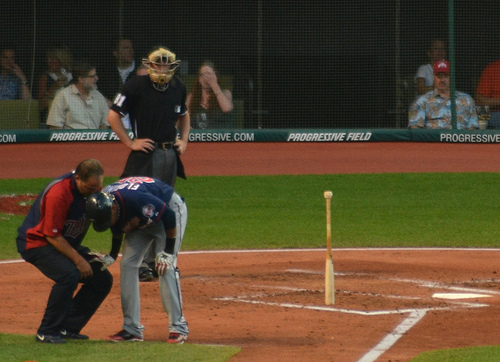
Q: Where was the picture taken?
A: It was taken at the field.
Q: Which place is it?
A: It is a field.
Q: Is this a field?
A: Yes, it is a field.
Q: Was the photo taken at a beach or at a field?
A: It was taken at a field.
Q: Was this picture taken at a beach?
A: No, the picture was taken in a field.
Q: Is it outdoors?
A: Yes, it is outdoors.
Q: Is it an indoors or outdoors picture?
A: It is outdoors.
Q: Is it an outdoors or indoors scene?
A: It is outdoors.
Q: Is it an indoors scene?
A: No, it is outdoors.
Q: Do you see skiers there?
A: No, there are no skiers.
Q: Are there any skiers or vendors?
A: No, there are no skiers or vendors.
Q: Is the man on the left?
A: Yes, the man is on the left of the image.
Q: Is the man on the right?
A: No, the man is on the left of the image.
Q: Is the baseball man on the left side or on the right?
A: The man is on the left of the image.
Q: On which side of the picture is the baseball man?
A: The man is on the left of the image.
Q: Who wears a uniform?
A: The man wears a uniform.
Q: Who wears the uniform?
A: The man wears a uniform.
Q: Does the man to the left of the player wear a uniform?
A: Yes, the man wears a uniform.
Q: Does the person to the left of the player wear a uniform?
A: Yes, the man wears a uniform.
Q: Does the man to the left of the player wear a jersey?
A: No, the man wears a uniform.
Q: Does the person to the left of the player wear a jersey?
A: No, the man wears a uniform.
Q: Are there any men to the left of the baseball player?
A: Yes, there is a man to the left of the player.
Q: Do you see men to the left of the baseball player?
A: Yes, there is a man to the left of the player.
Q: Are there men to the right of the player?
A: No, the man is to the left of the player.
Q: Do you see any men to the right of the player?
A: No, the man is to the left of the player.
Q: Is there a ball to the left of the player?
A: No, there is a man to the left of the player.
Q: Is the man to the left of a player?
A: Yes, the man is to the left of a player.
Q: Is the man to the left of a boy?
A: No, the man is to the left of a player.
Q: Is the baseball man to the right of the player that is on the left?
A: No, the man is to the left of the player.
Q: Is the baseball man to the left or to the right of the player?
A: The man is to the left of the player.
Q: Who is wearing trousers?
A: The man is wearing trousers.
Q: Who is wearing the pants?
A: The man is wearing trousers.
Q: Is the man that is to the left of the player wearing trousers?
A: Yes, the man is wearing trousers.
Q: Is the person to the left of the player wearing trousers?
A: Yes, the man is wearing trousers.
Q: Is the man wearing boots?
A: No, the man is wearing trousers.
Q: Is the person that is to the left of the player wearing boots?
A: No, the man is wearing trousers.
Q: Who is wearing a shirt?
A: The man is wearing a shirt.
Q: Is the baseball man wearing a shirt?
A: Yes, the man is wearing a shirt.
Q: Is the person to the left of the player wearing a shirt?
A: Yes, the man is wearing a shirt.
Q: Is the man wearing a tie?
A: No, the man is wearing a shirt.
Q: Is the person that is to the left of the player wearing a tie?
A: No, the man is wearing a shirt.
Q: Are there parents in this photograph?
A: No, there are no parents.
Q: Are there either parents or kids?
A: No, there are no parents or kids.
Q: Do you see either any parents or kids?
A: No, there are no parents or kids.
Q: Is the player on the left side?
A: Yes, the player is on the left of the image.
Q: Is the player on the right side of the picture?
A: No, the player is on the left of the image.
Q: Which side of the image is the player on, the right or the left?
A: The player is on the left of the image.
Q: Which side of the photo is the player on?
A: The player is on the left of the image.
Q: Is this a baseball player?
A: Yes, this is a baseball player.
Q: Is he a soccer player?
A: No, this is a baseball player.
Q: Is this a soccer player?
A: No, this is a baseball player.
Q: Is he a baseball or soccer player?
A: This is a baseball player.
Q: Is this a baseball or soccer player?
A: This is a baseball player.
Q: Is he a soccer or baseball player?
A: This is a baseball player.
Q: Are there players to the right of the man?
A: Yes, there is a player to the right of the man.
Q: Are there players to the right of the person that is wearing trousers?
A: Yes, there is a player to the right of the man.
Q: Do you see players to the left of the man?
A: No, the player is to the right of the man.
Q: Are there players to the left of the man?
A: No, the player is to the right of the man.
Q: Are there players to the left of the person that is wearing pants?
A: No, the player is to the right of the man.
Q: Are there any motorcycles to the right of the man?
A: No, there is a player to the right of the man.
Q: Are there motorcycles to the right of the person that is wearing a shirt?
A: No, there is a player to the right of the man.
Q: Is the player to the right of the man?
A: Yes, the player is to the right of the man.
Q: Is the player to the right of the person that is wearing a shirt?
A: Yes, the player is to the right of the man.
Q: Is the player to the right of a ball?
A: No, the player is to the right of the man.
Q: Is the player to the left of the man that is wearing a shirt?
A: No, the player is to the right of the man.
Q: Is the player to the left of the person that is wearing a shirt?
A: No, the player is to the right of the man.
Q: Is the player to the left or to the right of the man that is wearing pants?
A: The player is to the right of the man.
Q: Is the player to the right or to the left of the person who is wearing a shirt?
A: The player is to the right of the man.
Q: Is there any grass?
A: Yes, there is grass.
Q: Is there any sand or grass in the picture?
A: Yes, there is grass.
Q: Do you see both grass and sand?
A: No, there is grass but no sand.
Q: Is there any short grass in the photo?
A: Yes, there is short grass.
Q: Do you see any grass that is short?
A: Yes, there is short grass.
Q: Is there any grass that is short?
A: Yes, there is grass that is short.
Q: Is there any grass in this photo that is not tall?
A: Yes, there is short grass.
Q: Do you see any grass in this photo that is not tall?
A: Yes, there is short grass.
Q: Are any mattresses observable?
A: No, there are no mattresses.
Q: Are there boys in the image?
A: No, there are no boys.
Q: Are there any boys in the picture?
A: No, there are no boys.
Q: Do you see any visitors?
A: No, there are no visitors.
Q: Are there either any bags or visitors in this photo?
A: No, there are no visitors or bags.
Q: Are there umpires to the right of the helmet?
A: No, there is a lady to the right of the helmet.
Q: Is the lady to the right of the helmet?
A: Yes, the lady is to the right of the helmet.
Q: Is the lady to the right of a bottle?
A: No, the lady is to the right of the helmet.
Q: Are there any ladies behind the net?
A: Yes, there is a lady behind the net.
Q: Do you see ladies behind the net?
A: Yes, there is a lady behind the net.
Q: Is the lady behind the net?
A: Yes, the lady is behind the net.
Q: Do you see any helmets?
A: Yes, there is a helmet.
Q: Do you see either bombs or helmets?
A: Yes, there is a helmet.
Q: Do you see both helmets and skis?
A: No, there is a helmet but no skis.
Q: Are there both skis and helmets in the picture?
A: No, there is a helmet but no skis.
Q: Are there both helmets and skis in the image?
A: No, there is a helmet but no skis.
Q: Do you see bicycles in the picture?
A: No, there are no bicycles.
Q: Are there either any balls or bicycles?
A: No, there are no bicycles or balls.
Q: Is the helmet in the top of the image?
A: Yes, the helmet is in the top of the image.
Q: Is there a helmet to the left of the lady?
A: Yes, there is a helmet to the left of the lady.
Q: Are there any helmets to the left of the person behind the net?
A: Yes, there is a helmet to the left of the lady.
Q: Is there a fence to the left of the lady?
A: No, there is a helmet to the left of the lady.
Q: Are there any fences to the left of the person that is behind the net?
A: No, there is a helmet to the left of the lady.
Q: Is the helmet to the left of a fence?
A: No, the helmet is to the left of a lady.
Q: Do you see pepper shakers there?
A: No, there are no pepper shakers.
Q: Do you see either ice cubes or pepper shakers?
A: No, there are no pepper shakers or ice cubes.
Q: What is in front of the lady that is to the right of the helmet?
A: The net is in front of the lady.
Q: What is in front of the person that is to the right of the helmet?
A: The net is in front of the lady.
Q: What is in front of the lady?
A: The net is in front of the lady.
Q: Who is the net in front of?
A: The net is in front of the lady.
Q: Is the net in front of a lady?
A: Yes, the net is in front of a lady.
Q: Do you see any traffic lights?
A: No, there are no traffic lights.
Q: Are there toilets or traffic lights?
A: No, there are no traffic lights or toilets.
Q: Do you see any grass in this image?
A: Yes, there is grass.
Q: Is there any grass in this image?
A: Yes, there is grass.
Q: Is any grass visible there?
A: Yes, there is grass.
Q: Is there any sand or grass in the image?
A: Yes, there is grass.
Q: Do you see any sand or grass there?
A: Yes, there is grass.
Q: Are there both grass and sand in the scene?
A: No, there is grass but no sand.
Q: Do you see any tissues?
A: No, there are no tissues.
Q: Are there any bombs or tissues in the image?
A: No, there are no tissues or bombs.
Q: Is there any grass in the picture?
A: Yes, there is grass.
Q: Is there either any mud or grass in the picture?
A: Yes, there is grass.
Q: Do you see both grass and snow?
A: No, there is grass but no snow.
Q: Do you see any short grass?
A: Yes, there is short grass.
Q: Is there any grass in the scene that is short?
A: Yes, there is grass that is short.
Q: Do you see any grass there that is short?
A: Yes, there is grass that is short.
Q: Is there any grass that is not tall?
A: Yes, there is short grass.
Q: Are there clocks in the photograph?
A: No, there are no clocks.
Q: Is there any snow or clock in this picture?
A: No, there are no clocks or snow.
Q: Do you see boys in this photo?
A: No, there are no boys.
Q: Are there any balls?
A: No, there are no balls.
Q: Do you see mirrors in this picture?
A: No, there are no mirrors.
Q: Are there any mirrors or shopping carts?
A: No, there are no mirrors or shopping carts.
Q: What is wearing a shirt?
A: The fan is wearing a shirt.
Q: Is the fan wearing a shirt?
A: Yes, the fan is wearing a shirt.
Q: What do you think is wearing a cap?
A: The fan is wearing a cap.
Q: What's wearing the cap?
A: The fan is wearing a cap.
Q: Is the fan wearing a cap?
A: Yes, the fan is wearing a cap.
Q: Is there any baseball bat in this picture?
A: Yes, there is a baseball bat.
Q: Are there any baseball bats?
A: Yes, there is a baseball bat.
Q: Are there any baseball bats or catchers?
A: Yes, there is a baseball bat.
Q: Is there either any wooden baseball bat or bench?
A: Yes, there is a wood baseball bat.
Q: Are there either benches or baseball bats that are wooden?
A: Yes, the baseball bat is wooden.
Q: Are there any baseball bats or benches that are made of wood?
A: Yes, the baseball bat is made of wood.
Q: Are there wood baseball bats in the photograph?
A: Yes, there is a wood baseball bat.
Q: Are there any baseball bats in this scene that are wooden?
A: Yes, there is a baseball bat that is wooden.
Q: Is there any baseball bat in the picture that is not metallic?
A: Yes, there is a wooden baseball bat.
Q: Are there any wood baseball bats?
A: Yes, there is a baseball bat that is made of wood.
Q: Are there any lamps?
A: No, there are no lamps.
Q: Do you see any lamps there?
A: No, there are no lamps.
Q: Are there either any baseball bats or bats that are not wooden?
A: No, there is a baseball bat but it is wooden.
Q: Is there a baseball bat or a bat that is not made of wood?
A: No, there is a baseball bat but it is made of wood.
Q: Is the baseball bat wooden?
A: Yes, the baseball bat is wooden.